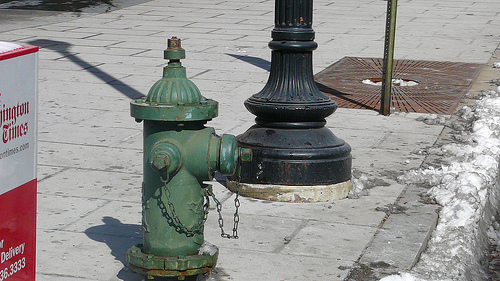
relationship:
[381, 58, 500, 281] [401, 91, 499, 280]
snow on curb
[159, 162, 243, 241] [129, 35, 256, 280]
chain on hydrant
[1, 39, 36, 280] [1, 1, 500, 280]
paper machine on sidewalk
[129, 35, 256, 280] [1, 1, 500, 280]
hydrant on sidewalk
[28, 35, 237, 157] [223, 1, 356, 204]
shadow of pole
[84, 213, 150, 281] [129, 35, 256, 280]
shadow of hydrant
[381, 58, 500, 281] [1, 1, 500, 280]
snow on sidewalk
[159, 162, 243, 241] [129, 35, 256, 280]
chain hanging off hydrant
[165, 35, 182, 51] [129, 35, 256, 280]
nozzle on hydrant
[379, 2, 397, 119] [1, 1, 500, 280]
pole on sidewalk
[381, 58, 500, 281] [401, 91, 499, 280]
snow along curb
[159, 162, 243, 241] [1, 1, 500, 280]
chain on sidewalk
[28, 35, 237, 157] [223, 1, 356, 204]
shadow from pole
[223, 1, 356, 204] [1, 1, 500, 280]
pole on sidewalk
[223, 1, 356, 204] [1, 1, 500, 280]
pole in sidewalk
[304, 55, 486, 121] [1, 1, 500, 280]
cover in sidewalk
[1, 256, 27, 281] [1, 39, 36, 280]
phone number on paper machine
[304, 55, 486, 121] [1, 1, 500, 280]
cover on sidewalk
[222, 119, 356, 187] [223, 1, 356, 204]
bottom of pole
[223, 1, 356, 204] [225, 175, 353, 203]
pole on concrete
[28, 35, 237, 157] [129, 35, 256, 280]
shadow of hydrant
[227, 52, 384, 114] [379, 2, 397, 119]
shadow of pole